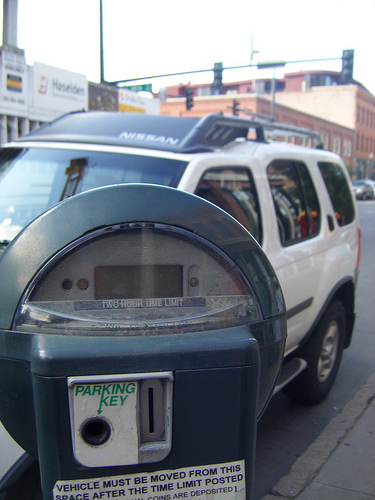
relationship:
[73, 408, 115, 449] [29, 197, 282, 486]
hole on meter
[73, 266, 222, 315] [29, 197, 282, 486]
notification on meter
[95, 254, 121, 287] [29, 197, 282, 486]
display on meter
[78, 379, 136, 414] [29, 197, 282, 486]
letters on meter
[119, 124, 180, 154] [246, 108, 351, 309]
nissan on vehicle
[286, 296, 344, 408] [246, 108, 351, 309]
tire on vehicle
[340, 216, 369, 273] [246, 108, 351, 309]
light on vehicle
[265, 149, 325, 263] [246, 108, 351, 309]
window on vehicle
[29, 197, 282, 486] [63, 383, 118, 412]
meter says parking key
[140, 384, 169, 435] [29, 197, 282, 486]
slot on meter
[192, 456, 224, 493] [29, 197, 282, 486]
notice on meter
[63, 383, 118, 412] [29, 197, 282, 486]
parking key on meter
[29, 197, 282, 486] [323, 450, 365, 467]
meter on sidewalk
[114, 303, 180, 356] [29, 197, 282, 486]
sign on meter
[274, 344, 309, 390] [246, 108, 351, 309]
step on vehicle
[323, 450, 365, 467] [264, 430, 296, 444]
sidewalk near road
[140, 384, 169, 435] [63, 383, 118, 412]
slot for parking key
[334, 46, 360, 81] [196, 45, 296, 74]
signals on pole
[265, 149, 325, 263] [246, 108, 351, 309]
window of vehicle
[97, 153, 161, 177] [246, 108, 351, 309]
windshield on vehicle